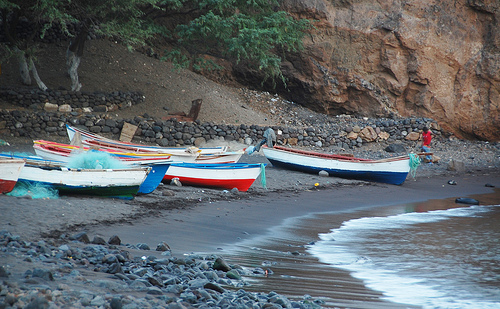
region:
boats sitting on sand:
[28, 135, 430, 210]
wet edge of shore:
[262, 191, 355, 238]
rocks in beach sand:
[144, 242, 257, 304]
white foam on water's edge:
[319, 241, 401, 288]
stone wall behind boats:
[160, 111, 304, 148]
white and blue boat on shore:
[348, 155, 422, 192]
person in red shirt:
[412, 124, 439, 152]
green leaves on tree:
[227, 11, 307, 68]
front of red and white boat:
[200, 166, 264, 193]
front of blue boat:
[150, 158, 175, 190]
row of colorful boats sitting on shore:
[0, 125, 430, 197]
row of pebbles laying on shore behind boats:
[0, 86, 437, 148]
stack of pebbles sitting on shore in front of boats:
[0, 220, 334, 307]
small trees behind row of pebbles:
[1, 0, 303, 87]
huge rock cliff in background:
[144, 0, 499, 144]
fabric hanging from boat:
[260, 160, 267, 187]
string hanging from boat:
[411, 152, 421, 182]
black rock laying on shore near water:
[456, 194, 478, 206]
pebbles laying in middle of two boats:
[155, 177, 185, 194]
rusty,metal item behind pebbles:
[163, 95, 201, 125]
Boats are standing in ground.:
[3, 111, 436, 207]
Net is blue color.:
[22, 143, 132, 216]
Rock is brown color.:
[333, 13, 468, 93]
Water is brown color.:
[334, 215, 491, 307]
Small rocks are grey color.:
[116, 249, 236, 307]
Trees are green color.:
[156, 17, 273, 54]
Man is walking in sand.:
[409, 119, 446, 171]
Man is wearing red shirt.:
[417, 124, 438, 156]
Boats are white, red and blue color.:
[34, 123, 411, 210]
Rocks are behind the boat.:
[162, 115, 375, 148]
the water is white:
[294, 185, 418, 292]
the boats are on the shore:
[30, 123, 411, 186]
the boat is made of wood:
[263, 125, 432, 175]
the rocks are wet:
[73, 219, 303, 301]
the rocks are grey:
[34, 215, 241, 295]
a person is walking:
[407, 112, 437, 162]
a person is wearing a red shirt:
[402, 109, 434, 161]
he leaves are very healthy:
[132, 3, 317, 94]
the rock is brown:
[275, 2, 478, 128]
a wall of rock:
[116, 100, 359, 147]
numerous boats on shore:
[28, 127, 410, 222]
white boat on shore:
[281, 152, 396, 189]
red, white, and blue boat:
[142, 157, 257, 184]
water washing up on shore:
[347, 188, 446, 304]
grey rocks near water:
[45, 221, 210, 306]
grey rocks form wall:
[60, 91, 317, 141]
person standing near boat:
[394, 147, 429, 186]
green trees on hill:
[148, 1, 313, 86]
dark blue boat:
[40, 138, 167, 188]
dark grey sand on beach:
[133, 183, 280, 243]